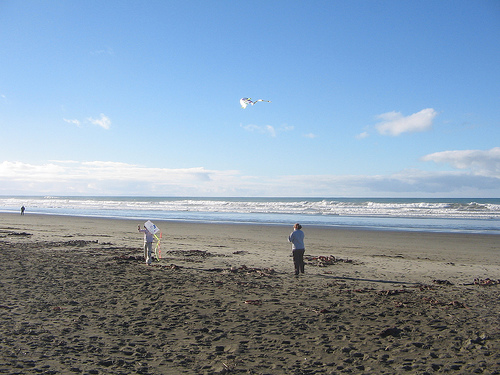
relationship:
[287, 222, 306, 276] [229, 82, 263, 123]
people flying a kite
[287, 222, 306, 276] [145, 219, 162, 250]
people holding a kite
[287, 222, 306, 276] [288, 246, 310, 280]
people wearing pants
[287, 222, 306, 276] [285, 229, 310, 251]
people wearing sweater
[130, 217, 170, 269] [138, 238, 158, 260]
person wearing pants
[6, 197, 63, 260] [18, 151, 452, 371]
person walking along beach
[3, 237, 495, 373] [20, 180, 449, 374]
prints in beach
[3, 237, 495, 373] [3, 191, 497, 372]
prints in beach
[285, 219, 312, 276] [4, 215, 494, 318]
people on beach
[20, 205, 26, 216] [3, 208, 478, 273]
person standing on edge